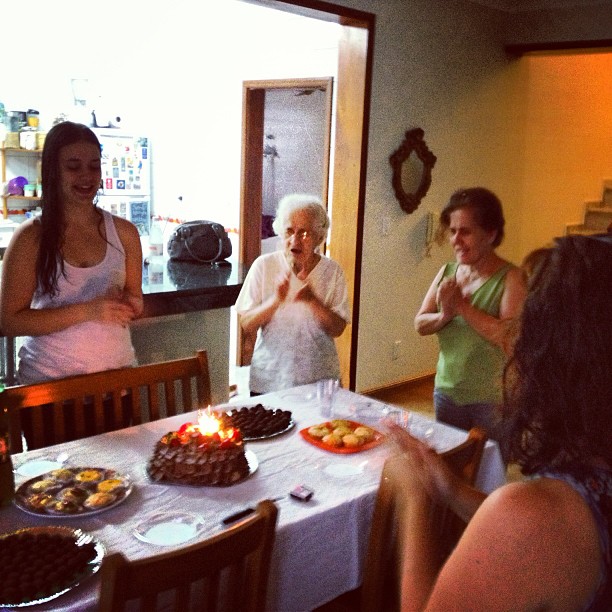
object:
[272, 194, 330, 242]
hair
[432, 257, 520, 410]
shirt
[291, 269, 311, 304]
hand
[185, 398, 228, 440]
candle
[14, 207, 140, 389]
shirt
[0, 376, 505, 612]
table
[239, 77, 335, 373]
doorway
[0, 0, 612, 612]
kitchen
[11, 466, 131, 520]
plate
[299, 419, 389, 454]
plate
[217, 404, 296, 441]
plate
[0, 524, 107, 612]
plate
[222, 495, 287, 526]
utensil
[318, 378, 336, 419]
vessel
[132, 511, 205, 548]
plate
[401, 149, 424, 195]
picture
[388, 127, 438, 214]
frame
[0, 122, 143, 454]
person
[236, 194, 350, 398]
person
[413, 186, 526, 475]
person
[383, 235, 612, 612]
person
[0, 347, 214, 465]
bench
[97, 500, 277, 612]
chair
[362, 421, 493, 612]
chair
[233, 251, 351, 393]
shirt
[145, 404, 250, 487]
birthday cake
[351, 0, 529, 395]
wall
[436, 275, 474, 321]
hands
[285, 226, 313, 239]
glasses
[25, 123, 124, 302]
hair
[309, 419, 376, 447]
cookies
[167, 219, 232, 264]
purse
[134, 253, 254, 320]
counter top